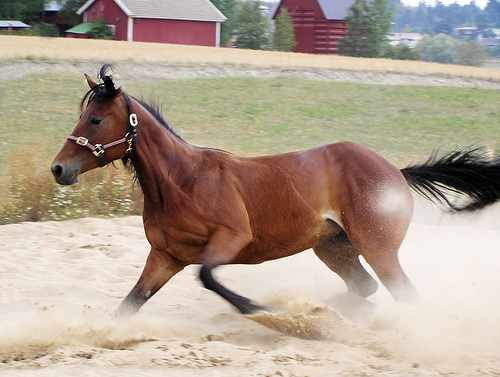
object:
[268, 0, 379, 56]
barn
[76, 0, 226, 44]
barn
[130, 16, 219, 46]
wall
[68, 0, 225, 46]
building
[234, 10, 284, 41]
shrubery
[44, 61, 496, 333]
horse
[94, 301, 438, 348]
hooves